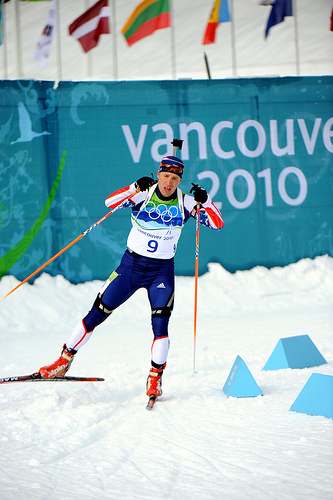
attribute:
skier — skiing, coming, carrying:
[64, 165, 274, 400]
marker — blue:
[209, 322, 303, 416]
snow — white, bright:
[62, 391, 253, 457]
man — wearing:
[84, 154, 211, 382]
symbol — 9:
[122, 230, 174, 262]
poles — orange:
[21, 220, 275, 324]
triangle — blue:
[254, 303, 329, 373]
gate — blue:
[18, 91, 325, 179]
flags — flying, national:
[51, 15, 322, 66]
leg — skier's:
[36, 289, 145, 419]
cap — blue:
[140, 126, 209, 183]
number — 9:
[124, 213, 207, 261]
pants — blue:
[83, 267, 202, 313]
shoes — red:
[23, 334, 201, 410]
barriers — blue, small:
[196, 296, 326, 427]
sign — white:
[117, 95, 313, 178]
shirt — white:
[104, 181, 205, 257]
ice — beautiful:
[185, 340, 327, 456]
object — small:
[279, 368, 319, 408]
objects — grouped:
[213, 328, 332, 443]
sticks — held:
[36, 218, 129, 301]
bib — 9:
[97, 221, 228, 279]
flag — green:
[119, 0, 188, 55]